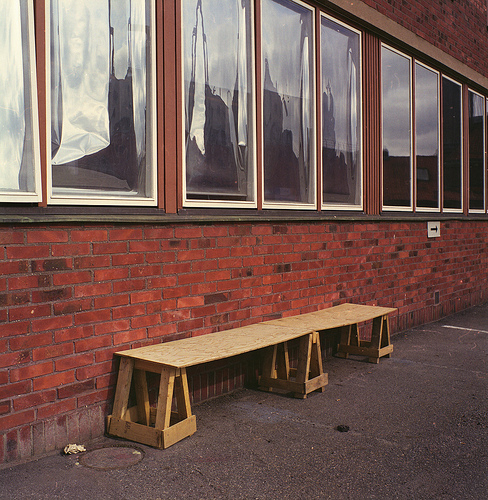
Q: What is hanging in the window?
A: Fabric.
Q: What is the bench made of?
A: Wood.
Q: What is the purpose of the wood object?
A: Bench.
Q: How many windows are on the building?
A: Nine.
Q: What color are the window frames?
A: Brown and white.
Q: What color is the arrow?
A: Black.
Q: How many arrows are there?
A: One.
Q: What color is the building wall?
A: Red.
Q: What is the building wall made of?
A: Brick.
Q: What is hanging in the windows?
A: Curtains.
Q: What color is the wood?
A: Brown.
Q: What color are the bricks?
A: Red.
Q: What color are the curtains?
A: White.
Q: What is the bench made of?
A: Wood.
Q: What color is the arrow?
A: Black.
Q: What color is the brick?
A: Red.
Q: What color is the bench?
A: Brown.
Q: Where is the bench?
A: In front of the wall.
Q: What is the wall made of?
A: Brick.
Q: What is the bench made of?
A: Wood.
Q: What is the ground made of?
A: Asphalt.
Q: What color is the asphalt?
A: Black.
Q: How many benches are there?
A: One.